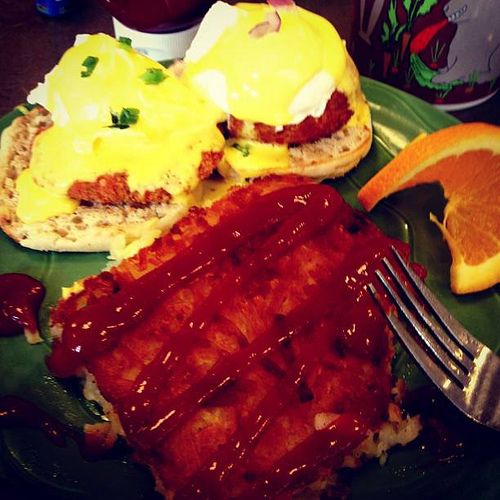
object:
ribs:
[42, 183, 343, 385]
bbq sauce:
[212, 324, 231, 352]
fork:
[365, 242, 499, 432]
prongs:
[391, 243, 485, 358]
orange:
[358, 120, 500, 293]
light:
[464, 347, 491, 405]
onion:
[103, 107, 139, 131]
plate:
[0, 74, 498, 498]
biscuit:
[0, 104, 203, 257]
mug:
[350, 0, 499, 112]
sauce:
[12, 6, 351, 233]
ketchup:
[0, 272, 43, 334]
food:
[0, 3, 500, 497]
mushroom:
[248, 11, 282, 39]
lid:
[111, 0, 205, 35]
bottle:
[109, 0, 208, 68]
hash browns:
[51, 176, 424, 498]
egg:
[185, 1, 345, 128]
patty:
[226, 91, 353, 144]